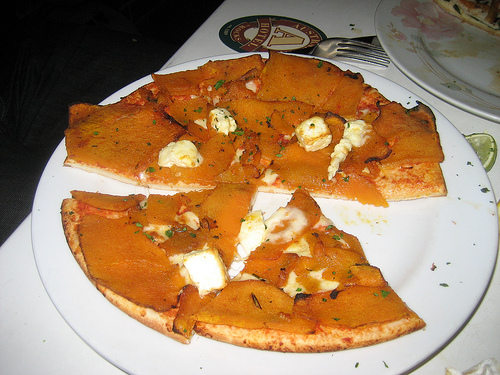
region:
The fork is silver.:
[310, 20, 376, 84]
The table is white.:
[308, 11, 348, 34]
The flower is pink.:
[370, 2, 474, 74]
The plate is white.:
[21, 43, 489, 370]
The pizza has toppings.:
[53, 157, 260, 337]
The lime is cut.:
[450, 120, 496, 156]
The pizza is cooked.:
[183, 284, 434, 357]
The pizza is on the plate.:
[60, 33, 467, 355]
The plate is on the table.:
[56, 28, 418, 373]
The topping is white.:
[290, 114, 339, 160]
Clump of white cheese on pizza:
[297, 115, 331, 152]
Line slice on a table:
[461, 128, 496, 173]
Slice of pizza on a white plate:
[211, 188, 423, 352]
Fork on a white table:
[309, 37, 396, 68]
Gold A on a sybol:
[268, 23, 308, 46]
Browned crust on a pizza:
[193, 320, 273, 347]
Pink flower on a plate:
[396, 0, 467, 42]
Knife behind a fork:
[345, 27, 396, 49]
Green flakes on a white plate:
[423, 258, 455, 288]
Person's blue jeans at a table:
[21, 32, 182, 116]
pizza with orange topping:
[143, 90, 323, 344]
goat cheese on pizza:
[286, 105, 376, 196]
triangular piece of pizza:
[65, 180, 228, 331]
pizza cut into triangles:
[115, 75, 370, 350]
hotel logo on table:
[231, 10, 316, 50]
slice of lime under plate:
[451, 112, 479, 162]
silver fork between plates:
[301, 30, 392, 75]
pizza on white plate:
[122, 50, 452, 297]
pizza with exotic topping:
[91, 105, 418, 350]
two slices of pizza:
[87, 186, 406, 356]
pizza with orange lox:
[57, 54, 428, 336]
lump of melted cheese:
[157, 138, 202, 168]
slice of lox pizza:
[204, 186, 423, 351]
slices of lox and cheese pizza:
[61, 53, 445, 349]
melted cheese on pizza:
[268, 206, 310, 244]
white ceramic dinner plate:
[33, 58, 498, 373]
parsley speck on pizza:
[210, 78, 226, 90]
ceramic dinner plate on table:
[377, 3, 497, 120]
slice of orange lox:
[69, 101, 175, 172]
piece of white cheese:
[176, 236, 226, 310]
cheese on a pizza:
[292, 110, 336, 152]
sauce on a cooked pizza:
[70, 192, 152, 229]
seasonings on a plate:
[425, 238, 460, 293]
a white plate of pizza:
[32, 12, 499, 374]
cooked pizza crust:
[193, 307, 431, 364]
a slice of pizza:
[192, 182, 439, 356]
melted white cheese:
[323, 103, 378, 180]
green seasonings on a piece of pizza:
[79, 118, 169, 163]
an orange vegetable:
[61, 200, 204, 318]